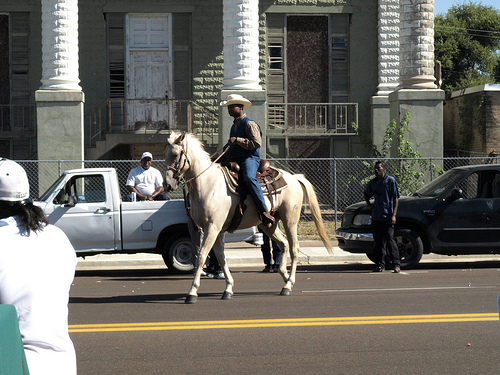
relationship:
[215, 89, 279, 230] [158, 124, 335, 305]
man riding a horse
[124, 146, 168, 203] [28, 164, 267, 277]
man sitting in a truck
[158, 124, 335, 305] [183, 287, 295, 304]
horse has hooves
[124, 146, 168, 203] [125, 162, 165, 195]
man wearing a shirt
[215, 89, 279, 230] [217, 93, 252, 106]
man wearing a cowboy hat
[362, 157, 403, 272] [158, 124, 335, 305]
man stands behind horse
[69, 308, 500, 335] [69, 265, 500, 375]
lines are on street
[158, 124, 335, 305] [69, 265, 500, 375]
horse on street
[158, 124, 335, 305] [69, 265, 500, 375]
horse in street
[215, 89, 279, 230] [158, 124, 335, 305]
man on horse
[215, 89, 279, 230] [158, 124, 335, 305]
man riding horse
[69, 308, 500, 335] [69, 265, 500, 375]
lines on street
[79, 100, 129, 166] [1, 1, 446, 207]
stairs are on building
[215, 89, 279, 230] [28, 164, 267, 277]
man sitting on truck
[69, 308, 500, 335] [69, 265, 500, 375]
lines are painted on street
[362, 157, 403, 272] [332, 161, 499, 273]
man leaning on suv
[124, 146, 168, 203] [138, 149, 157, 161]
man wearing a hat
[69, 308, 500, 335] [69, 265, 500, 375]
lines are in street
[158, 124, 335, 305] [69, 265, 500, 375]
horse walking in street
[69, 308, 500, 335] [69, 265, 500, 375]
lines are on center of street